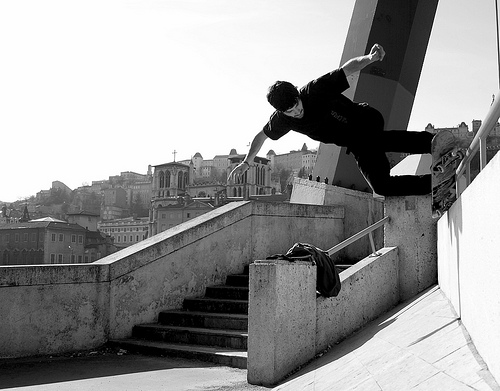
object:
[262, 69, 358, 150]
shirt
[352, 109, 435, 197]
pants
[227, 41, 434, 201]
man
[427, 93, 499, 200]
rail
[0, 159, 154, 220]
buildings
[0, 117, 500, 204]
skyline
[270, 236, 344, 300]
clothes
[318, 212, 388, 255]
rail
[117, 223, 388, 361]
stairs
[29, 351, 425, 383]
surface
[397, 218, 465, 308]
air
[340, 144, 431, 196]
left leg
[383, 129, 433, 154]
right leg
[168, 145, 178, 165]
cross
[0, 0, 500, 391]
city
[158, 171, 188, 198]
arches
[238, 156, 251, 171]
wrist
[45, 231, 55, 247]
window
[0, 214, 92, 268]
building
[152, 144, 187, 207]
building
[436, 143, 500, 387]
wall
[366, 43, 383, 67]
hand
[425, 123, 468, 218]
skateboard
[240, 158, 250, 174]
watch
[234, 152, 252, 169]
man's wrist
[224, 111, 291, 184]
arms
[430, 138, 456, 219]
graffiti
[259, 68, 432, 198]
trick